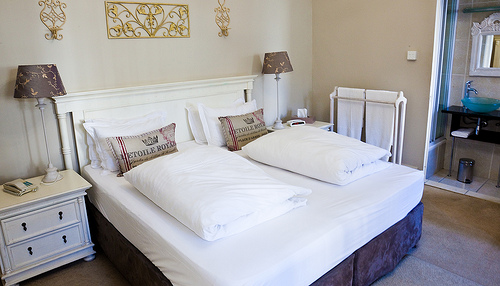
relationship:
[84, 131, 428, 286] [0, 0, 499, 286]
bed inside a bathroom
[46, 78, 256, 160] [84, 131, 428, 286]
headboard behind a bed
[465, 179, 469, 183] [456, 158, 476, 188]
foot pedal at bottom of trashcan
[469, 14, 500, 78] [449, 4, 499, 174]
mirror hanging on wall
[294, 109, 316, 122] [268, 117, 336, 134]
box of tissues on top of a nightstand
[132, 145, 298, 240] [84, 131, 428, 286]
bedding on top of bed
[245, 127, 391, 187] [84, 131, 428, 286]
bedding on top of bed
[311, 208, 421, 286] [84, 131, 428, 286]
bedskirt at bottom of bed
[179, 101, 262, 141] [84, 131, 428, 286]
pillows on top of bed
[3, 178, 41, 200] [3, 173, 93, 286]
telephone on top of nightstand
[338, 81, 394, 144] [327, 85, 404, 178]
towels are hanging on rack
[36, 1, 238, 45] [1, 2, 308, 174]
decorations are hanging on wall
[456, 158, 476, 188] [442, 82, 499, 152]
trashcan underneath sink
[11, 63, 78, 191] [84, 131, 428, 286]
lamp to left of bed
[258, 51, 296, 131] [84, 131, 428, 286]
lamp to right of bed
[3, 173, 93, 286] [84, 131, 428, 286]
nightstand to left of a bed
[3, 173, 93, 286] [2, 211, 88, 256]
nightstand has drawers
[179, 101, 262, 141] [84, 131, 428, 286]
pillows are at head of a bed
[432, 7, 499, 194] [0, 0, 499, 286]
bathroom adjacent to bathroom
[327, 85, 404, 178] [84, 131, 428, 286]
rack right of bed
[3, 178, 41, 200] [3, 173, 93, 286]
telephone sitting on top of nightstand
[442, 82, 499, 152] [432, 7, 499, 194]
sink inside bathroom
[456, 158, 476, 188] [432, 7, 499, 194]
trashcan inside bathroom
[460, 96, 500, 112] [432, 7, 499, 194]
sink inside bathroom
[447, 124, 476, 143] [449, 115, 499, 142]
towel within shelf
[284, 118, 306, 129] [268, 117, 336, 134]
alarm clock on top of nightstand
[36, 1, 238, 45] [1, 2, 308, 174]
decorations are on wall